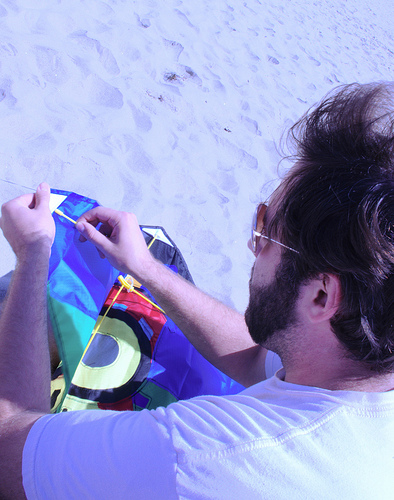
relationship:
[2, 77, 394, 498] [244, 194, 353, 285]
man wearing glasses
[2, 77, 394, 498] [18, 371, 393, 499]
man wearing shirt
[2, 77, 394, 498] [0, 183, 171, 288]
man has hands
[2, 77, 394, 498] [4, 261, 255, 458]
man has arms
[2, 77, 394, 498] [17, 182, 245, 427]
man fixing kite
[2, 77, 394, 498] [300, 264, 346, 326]
man has ear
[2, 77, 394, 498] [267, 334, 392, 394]
man has neck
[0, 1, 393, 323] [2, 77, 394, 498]
sand below man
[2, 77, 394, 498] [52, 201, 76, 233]
man inserting piece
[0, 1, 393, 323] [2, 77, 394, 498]
sand near man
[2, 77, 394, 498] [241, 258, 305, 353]
man has a beard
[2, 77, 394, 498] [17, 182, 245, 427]
man working on kite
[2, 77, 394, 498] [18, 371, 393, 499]
man wearing white shirt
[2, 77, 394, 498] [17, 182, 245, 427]
man assembling kite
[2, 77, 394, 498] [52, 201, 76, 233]
man holding piece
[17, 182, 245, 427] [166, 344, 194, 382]
kite colored blue